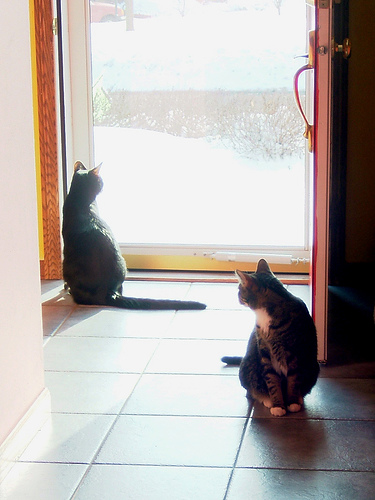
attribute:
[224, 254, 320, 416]
cat — black, gray,  gray, black and white, sitting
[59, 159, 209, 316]
cat — staring, black, looking, sitting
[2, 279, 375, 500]
floor —   tiled,  tiled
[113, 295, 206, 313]
tail —  long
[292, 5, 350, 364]
door — wooden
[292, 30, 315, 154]
handle —  door's, brass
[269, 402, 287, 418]
paw — white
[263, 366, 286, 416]
fore leg —  the fore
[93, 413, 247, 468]
tile — white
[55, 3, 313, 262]
window — large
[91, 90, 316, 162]
plants —  covering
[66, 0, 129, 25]
car — parked